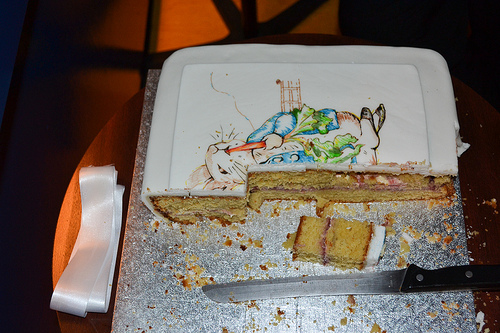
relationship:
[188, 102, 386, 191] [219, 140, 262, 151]
bunny rabbit holding carrot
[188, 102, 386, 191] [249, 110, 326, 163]
bunny rabbit wearing a coat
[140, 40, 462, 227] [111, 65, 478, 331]
cake on tray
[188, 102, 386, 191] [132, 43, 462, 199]
bunny rabbit on frosting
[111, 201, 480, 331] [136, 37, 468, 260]
tray on bottom of cake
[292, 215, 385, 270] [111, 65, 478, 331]
slice on tray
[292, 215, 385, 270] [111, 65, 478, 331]
slice of tray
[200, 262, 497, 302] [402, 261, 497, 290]
knife with handle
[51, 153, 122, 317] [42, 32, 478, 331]
ribbon sitting on table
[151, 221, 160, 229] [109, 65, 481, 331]
crumb on sheet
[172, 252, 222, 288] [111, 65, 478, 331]
crumbs on tray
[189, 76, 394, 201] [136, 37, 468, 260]
drawing on cake